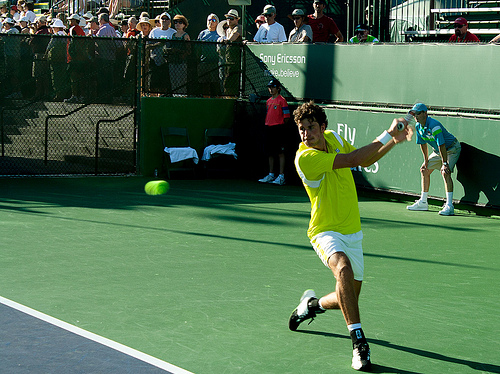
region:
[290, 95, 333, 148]
the head of a man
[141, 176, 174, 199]
a green tennis ball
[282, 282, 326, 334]
a black and white tennis shoe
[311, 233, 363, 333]
the leg of a man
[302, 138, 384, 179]
the arm of a man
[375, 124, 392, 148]
a white wrist band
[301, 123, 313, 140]
the nose of a man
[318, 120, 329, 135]
the ear of a man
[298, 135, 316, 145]
the mouth of a man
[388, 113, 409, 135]
the hand of a man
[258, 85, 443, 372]
adult male tennis player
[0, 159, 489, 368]
hardcourt tennis court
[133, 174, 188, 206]
tennis ball in motion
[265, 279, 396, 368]
tennis shoes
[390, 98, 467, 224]
ball boy for a tennis match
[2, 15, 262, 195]
crowd control fence at a tennis match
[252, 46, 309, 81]
advertisement for Sony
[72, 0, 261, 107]
tennis fans taking in a match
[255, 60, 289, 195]
ball boy for a tennis match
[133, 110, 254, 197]
towels for players at a tennis court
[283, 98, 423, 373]
The man is running.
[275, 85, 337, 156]
The man has hair.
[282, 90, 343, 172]
The man's hair is curly.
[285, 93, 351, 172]
The man's hair is brown.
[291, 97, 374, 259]
The man is wearing a shirt.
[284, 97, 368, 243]
The man's shirt is yellow and white.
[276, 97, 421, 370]
The man is wearing shorts.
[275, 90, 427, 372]
The man's shorts are white.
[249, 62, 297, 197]
The man is standing.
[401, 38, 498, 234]
The man is standing against the barrier wall.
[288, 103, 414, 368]
Male athlete preparing to hit tennis ball with racket.